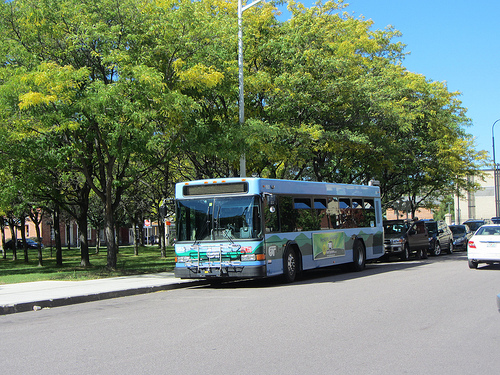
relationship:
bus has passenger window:
[176, 176, 388, 288] [296, 200, 314, 231]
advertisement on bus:
[310, 229, 346, 260] [176, 176, 388, 288]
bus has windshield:
[176, 176, 388, 288] [178, 201, 262, 242]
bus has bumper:
[176, 176, 388, 288] [174, 236, 265, 281]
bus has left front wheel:
[176, 176, 388, 288] [282, 241, 301, 280]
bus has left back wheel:
[176, 176, 388, 288] [351, 235, 369, 270]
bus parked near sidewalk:
[176, 176, 388, 288] [2, 268, 209, 309]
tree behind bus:
[166, 8, 405, 188] [176, 176, 388, 288]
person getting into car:
[411, 213, 427, 261] [385, 217, 430, 261]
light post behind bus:
[239, 1, 260, 172] [176, 176, 388, 288]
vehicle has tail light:
[465, 223, 500, 271] [468, 238, 478, 249]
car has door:
[385, 217, 430, 261] [406, 216, 431, 252]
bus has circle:
[176, 176, 388, 288] [239, 176, 247, 184]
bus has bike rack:
[176, 176, 388, 288] [186, 243, 246, 270]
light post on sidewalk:
[239, 1, 260, 172] [2, 268, 209, 309]